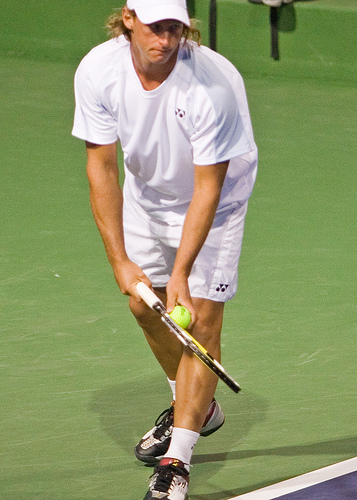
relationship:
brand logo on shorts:
[213, 282, 228, 292] [75, 185, 270, 293]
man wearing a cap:
[68, 7, 265, 493] [125, 0, 191, 29]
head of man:
[122, 0, 185, 65] [68, 7, 265, 493]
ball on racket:
[165, 299, 194, 331] [127, 280, 232, 348]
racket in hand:
[132, 280, 245, 395] [164, 273, 198, 327]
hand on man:
[109, 258, 154, 302] [70, 0, 259, 497]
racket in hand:
[132, 280, 245, 395] [109, 258, 154, 302]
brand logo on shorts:
[213, 282, 228, 292] [120, 182, 248, 301]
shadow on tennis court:
[86, 367, 269, 491] [2, 9, 345, 495]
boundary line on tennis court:
[230, 455, 355, 498] [2, 9, 345, 495]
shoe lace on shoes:
[153, 464, 182, 488] [134, 397, 225, 499]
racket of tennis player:
[132, 280, 245, 395] [68, 4, 304, 472]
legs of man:
[132, 286, 236, 497] [68, 7, 265, 493]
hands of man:
[116, 254, 203, 338] [75, 1, 253, 422]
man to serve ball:
[70, 0, 259, 497] [162, 301, 192, 329]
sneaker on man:
[142, 458, 190, 499] [70, 0, 259, 497]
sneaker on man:
[132, 394, 226, 463] [70, 0, 259, 497]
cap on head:
[125, 0, 191, 29] [111, 0, 196, 69]